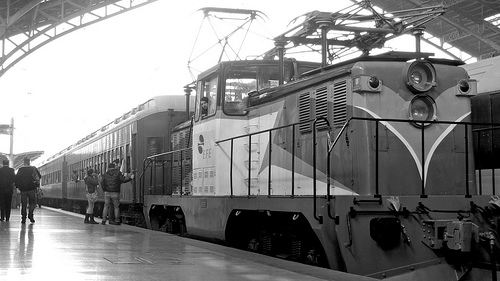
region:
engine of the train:
[168, 49, 470, 253]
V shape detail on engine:
[353, 60, 485, 219]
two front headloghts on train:
[405, 70, 445, 135]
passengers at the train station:
[3, 150, 131, 234]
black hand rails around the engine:
[221, 109, 353, 220]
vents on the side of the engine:
[285, 83, 353, 132]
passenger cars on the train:
[36, 128, 183, 205]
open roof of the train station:
[48, 9, 295, 171]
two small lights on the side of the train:
[356, 68, 477, 98]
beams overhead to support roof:
[3, 2, 101, 62]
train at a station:
[46, 39, 486, 269]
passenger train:
[39, 42, 473, 272]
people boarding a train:
[79, 150, 157, 242]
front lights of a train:
[403, 53, 439, 130]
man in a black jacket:
[12, 140, 42, 225]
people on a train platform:
[0, 120, 135, 255]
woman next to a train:
[80, 155, 100, 225]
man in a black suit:
[0, 155, 15, 225]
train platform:
[0, 185, 326, 275]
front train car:
[172, 37, 490, 277]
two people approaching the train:
[79, 158, 136, 230]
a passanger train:
[31, 39, 494, 279]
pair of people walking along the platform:
[0, 155, 44, 229]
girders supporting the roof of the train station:
[0, 1, 172, 90]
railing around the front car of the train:
[138, 118, 498, 211]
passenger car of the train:
[61, 90, 193, 234]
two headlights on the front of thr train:
[400, 51, 443, 132]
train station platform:
[0, 190, 416, 279]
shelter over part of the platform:
[0, 110, 47, 210]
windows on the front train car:
[191, 56, 333, 124]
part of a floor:
[141, 224, 185, 255]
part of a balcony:
[215, 141, 264, 194]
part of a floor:
[76, 205, 129, 248]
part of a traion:
[223, 173, 276, 228]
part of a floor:
[90, 210, 147, 252]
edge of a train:
[180, 162, 264, 244]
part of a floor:
[63, 220, 113, 262]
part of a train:
[268, 130, 321, 192]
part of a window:
[190, 73, 213, 95]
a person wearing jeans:
[16, 190, 41, 216]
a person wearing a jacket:
[103, 168, 122, 186]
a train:
[130, 63, 431, 200]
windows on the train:
[63, 160, 106, 173]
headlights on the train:
[408, 66, 448, 122]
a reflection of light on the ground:
[11, 237, 91, 275]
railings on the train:
[147, 153, 176, 188]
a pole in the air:
[2, 110, 24, 152]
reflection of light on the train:
[67, 145, 115, 155]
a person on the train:
[193, 91, 215, 113]